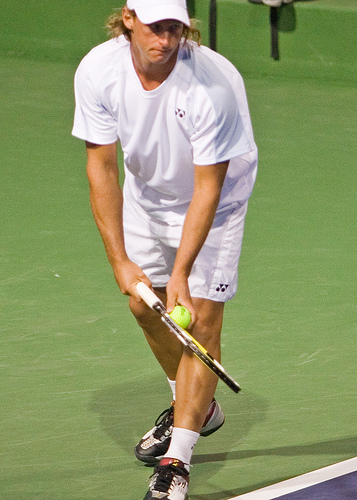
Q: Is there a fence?
A: No, there are no fences.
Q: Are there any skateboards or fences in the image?
A: No, there are no fences or skateboards.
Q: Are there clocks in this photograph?
A: No, there are no clocks.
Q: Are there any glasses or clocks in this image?
A: No, there are no clocks or glasses.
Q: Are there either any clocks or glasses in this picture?
A: No, there are no clocks or glasses.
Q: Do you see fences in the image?
A: No, there are no fences.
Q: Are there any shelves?
A: No, there are no shelves.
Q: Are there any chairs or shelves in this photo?
A: No, there are no shelves or chairs.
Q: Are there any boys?
A: No, there are no boys.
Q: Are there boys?
A: No, there are no boys.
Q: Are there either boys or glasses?
A: No, there are no boys or glasses.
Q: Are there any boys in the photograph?
A: No, there are no boys.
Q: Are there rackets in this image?
A: Yes, there is a racket.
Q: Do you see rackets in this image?
A: Yes, there is a racket.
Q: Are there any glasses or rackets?
A: Yes, there is a racket.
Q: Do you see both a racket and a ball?
A: Yes, there are both a racket and a ball.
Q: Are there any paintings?
A: No, there are no paintings.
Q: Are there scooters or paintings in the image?
A: No, there are no paintings or scooters.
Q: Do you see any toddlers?
A: No, there are no toddlers.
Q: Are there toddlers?
A: No, there are no toddlers.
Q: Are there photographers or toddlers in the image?
A: No, there are no toddlers or photographers.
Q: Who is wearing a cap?
A: The man is wearing a cap.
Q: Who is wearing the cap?
A: The man is wearing a cap.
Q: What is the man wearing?
A: The man is wearing a cap.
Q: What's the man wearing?
A: The man is wearing a cap.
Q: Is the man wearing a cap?
A: Yes, the man is wearing a cap.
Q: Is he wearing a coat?
A: No, the man is wearing a cap.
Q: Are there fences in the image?
A: No, there are no fences.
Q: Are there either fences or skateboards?
A: No, there are no fences or skateboards.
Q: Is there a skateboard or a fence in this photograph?
A: No, there are no fences or skateboards.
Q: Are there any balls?
A: Yes, there is a ball.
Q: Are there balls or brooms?
A: Yes, there is a ball.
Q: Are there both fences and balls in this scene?
A: No, there is a ball but no fences.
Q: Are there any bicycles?
A: No, there are no bicycles.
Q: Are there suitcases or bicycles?
A: No, there are no bicycles or suitcases.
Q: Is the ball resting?
A: Yes, the ball is resting.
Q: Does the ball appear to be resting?
A: Yes, the ball is resting.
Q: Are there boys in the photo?
A: No, there are no boys.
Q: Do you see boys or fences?
A: No, there are no boys or fences.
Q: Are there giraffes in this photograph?
A: No, there are no giraffes.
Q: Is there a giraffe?
A: No, there are no giraffes.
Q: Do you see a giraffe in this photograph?
A: No, there are no giraffes.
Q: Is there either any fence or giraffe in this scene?
A: No, there are no giraffes or fences.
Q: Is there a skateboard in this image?
A: No, there are no skateboards.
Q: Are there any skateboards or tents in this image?
A: No, there are no skateboards or tents.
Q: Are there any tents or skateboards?
A: No, there are no skateboards or tents.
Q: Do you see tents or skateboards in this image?
A: No, there are no skateboards or tents.